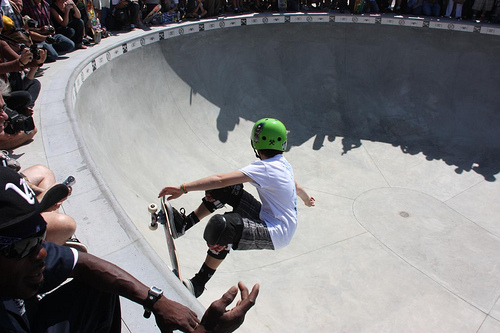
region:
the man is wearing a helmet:
[246, 113, 289, 155]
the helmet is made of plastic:
[247, 117, 286, 154]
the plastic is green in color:
[250, 117, 288, 153]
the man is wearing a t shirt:
[242, 153, 301, 248]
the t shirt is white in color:
[242, 152, 300, 244]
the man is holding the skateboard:
[155, 160, 297, 290]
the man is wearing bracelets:
[180, 181, 188, 197]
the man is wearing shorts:
[215, 180, 277, 251]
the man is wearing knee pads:
[205, 172, 246, 250]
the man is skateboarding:
[143, 115, 299, 293]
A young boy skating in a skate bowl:
[137, 113, 317, 303]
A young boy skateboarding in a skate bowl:
[145, 115, 328, 307]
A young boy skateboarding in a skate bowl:
[143, 109, 323, 304]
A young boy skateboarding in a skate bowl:
[145, 111, 324, 308]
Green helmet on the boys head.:
[276, 109, 301, 180]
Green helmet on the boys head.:
[289, 264, 303, 301]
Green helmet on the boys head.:
[19, 149, 44, 253]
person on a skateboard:
[140, 107, 338, 312]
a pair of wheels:
[140, 200, 162, 235]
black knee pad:
[195, 206, 239, 256]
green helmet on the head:
[246, 116, 294, 159]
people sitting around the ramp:
[0, 0, 498, 331]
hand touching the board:
[156, 181, 181, 208]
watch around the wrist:
[140, 283, 166, 323]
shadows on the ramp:
[161, 26, 497, 186]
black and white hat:
[0, 158, 80, 235]